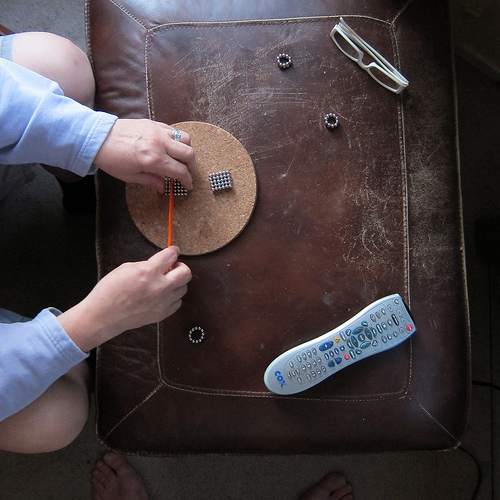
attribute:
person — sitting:
[0, 31, 200, 453]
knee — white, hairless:
[33, 28, 94, 97]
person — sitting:
[11, 30, 101, 372]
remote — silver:
[264, 288, 416, 396]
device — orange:
[166, 173, 173, 279]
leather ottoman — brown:
[241, 83, 424, 329]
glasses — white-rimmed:
[328, 16, 409, 96]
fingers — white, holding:
[145, 247, 190, 324]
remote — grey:
[224, 264, 424, 414]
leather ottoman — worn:
[87, 4, 476, 461]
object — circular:
[185, 323, 209, 351]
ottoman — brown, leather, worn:
[81, 2, 483, 471]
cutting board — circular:
[128, 119, 259, 259]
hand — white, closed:
[96, 109, 198, 191]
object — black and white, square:
[207, 167, 234, 192]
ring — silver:
[170, 127, 180, 140]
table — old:
[82, 10, 479, 455]